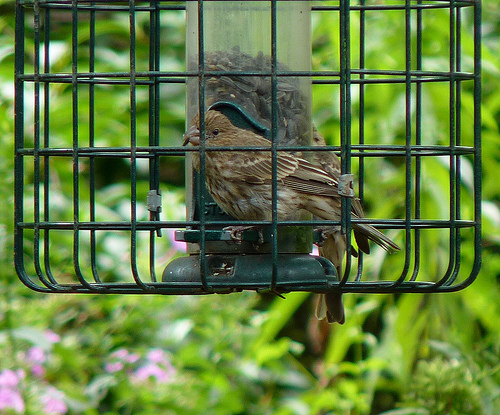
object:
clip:
[333, 169, 358, 198]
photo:
[0, 1, 500, 414]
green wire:
[340, 0, 347, 178]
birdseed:
[208, 45, 293, 98]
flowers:
[29, 363, 50, 379]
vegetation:
[0, 0, 500, 414]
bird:
[182, 108, 401, 260]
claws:
[221, 225, 239, 231]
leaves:
[260, 336, 294, 367]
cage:
[9, 0, 485, 299]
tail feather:
[310, 293, 350, 324]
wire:
[11, 1, 29, 292]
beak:
[178, 129, 193, 147]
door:
[154, 0, 354, 230]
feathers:
[234, 151, 297, 184]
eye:
[213, 127, 220, 137]